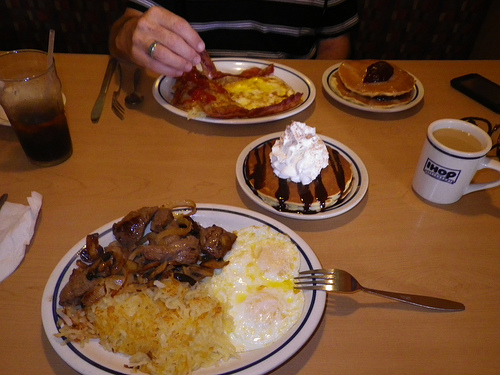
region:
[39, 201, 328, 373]
A plate of food.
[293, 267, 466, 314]
A silver metal fork.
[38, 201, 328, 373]
A white plate with a black border.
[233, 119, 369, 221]
A plate of pancakes with chocolate syrup and whipped cream.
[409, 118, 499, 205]
A white coffee cup.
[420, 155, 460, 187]
An IHOP logo is on the coffee cup.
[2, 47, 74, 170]
A glass filled with brown liquid.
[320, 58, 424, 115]
A plate of pancakes.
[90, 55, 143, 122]
A knife, fork and spoon.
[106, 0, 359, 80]
A person is holding a piece of bacon.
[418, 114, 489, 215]
this is a cup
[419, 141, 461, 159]
the cup is white in color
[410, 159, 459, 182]
this is a writing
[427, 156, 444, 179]
the writing is in black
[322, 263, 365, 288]
the fox is metallic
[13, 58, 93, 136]
this is a glass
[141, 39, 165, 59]
this is a ring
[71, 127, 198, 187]
this is the table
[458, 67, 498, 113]
this is a phone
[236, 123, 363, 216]
Pancakes on a plate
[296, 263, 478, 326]
forks on a plate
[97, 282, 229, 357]
hash browns on a plate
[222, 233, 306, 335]
eggs on a plate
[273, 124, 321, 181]
whip cream on top of pancakes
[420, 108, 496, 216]
coffee in a mug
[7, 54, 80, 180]
cup with soda in it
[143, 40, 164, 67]
person wearing a wedding ring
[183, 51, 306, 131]
bacon and eggs on a plate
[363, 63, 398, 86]
jelly on pancakes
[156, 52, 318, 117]
THE BACON AND EGGS ARE ON THE PLATE TOGETHER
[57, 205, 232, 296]
THE MUSHROOMS AND ONIONS ARE ON THE STEAK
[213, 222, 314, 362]
THE EGGS ARE RUNNY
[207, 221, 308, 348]
THE EGGS ARE ON THE PLATE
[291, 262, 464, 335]
THE FORK IS PROPPED ON THE PLATE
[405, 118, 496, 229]
THE COFFEE IS IN THE CUP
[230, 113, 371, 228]
THE WHIPPED CREAM IS ON THE PANCAKES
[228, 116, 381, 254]
THE CHOCOLATE IS ON THE PANCAKES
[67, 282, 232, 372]
THE HASH BROWNS ARE ON THE TABLE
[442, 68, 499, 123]
THE CELL PHONE IS ON THE TABLE